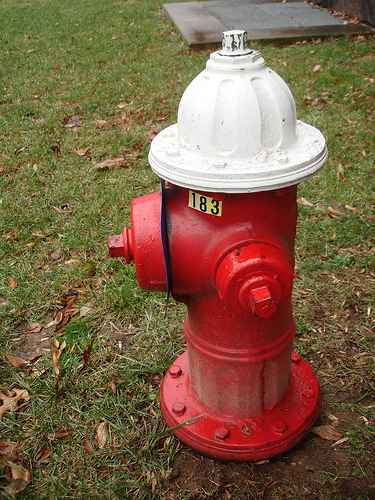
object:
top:
[147, 28, 330, 199]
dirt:
[171, 427, 374, 499]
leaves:
[90, 415, 108, 451]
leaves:
[0, 383, 29, 420]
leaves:
[3, 351, 26, 372]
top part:
[217, 30, 253, 58]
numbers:
[207, 198, 220, 218]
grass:
[0, 0, 374, 499]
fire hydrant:
[105, 29, 328, 464]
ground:
[0, 0, 374, 498]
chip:
[239, 422, 250, 436]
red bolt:
[214, 425, 229, 438]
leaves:
[339, 15, 361, 27]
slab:
[162, 0, 371, 52]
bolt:
[221, 28, 247, 55]